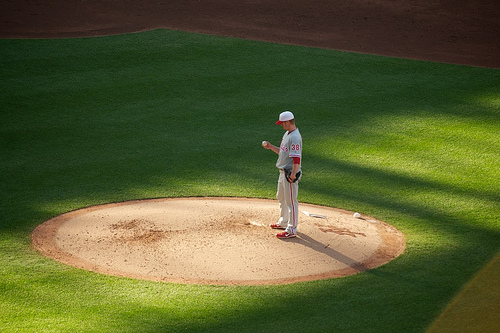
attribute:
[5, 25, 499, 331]
grass — green, manicured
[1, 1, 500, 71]
dirt — brown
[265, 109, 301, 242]
player — standing, pitcher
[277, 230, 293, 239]
shoe — red, white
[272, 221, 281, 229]
shoe — red, white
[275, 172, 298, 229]
pants — white, red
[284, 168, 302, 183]
glove — black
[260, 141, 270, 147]
ball — white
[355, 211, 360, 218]
tissue — white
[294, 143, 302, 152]
number — 38, red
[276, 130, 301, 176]
shirt — gray, red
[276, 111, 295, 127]
hat — white, red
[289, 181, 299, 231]
stripe — red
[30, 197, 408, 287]
mound — round, pitcher, pitcher's